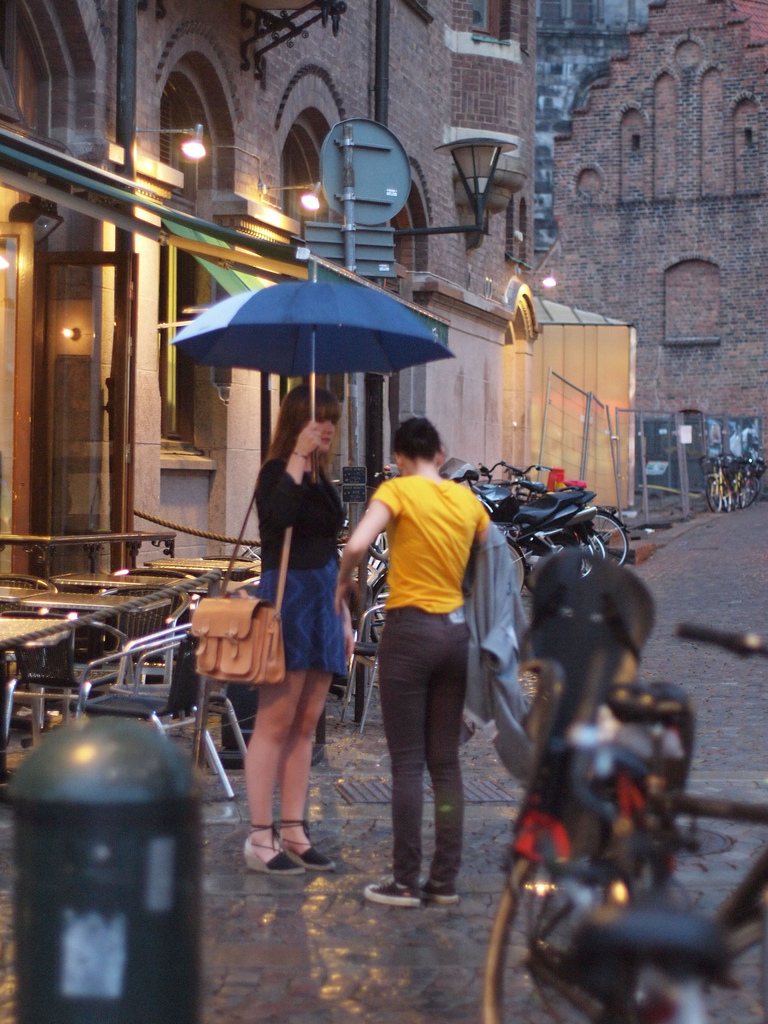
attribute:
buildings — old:
[12, 1, 765, 401]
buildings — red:
[608, 17, 753, 193]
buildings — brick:
[562, 121, 747, 379]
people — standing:
[142, 272, 539, 911]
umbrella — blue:
[167, 280, 453, 451]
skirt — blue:
[232, 555, 366, 683]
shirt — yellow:
[342, 474, 496, 615]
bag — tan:
[177, 560, 299, 709]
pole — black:
[409, 130, 487, 241]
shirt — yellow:
[313, 470, 552, 742]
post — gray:
[280, 139, 459, 279]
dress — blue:
[201, 384, 422, 822]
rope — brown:
[23, 564, 262, 684]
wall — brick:
[15, 310, 113, 388]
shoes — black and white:
[326, 430, 556, 930]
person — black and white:
[236, 426, 604, 875]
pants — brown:
[363, 601, 479, 878]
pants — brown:
[373, 593, 490, 882]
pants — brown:
[368, 600, 484, 888]